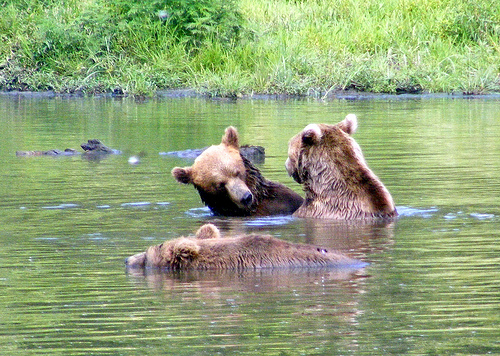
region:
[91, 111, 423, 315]
bears in the water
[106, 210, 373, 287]
bear that is almost completely submerged in the water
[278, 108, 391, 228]
head sticking out of the water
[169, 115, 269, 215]
head tilted to the side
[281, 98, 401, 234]
brown fur on the bear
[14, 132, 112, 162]
rocks sticking out of the water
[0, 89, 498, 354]
green body of water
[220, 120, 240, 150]
ear sticking off the top of the head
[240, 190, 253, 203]
black nose on the snout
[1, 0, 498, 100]
vegetation along the shore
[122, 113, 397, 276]
Three brown bears in water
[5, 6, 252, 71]
Green bushes along water's edge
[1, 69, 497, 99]
Green grass along water's edge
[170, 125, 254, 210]
Brown bear's head and face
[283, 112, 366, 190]
Brown bear facing away from camera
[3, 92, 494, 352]
Water reflecting the green grass and bushes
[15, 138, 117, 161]
Black and gray rocks in the water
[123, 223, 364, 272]
Brown bear partially submerged in water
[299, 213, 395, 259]
Reflection of brown bear in water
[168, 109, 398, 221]
Two bears next to each other in the water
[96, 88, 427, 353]
Three bears in the water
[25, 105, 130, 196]
The water is calm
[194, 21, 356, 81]
The weeds are green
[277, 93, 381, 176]
The bear has 2 ears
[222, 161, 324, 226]
The bear is wet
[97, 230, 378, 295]
The bear is mostly in the water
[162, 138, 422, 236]
The bears are togetehr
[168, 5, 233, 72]
The leaves are green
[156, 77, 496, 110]
The bank of the water is green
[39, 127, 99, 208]
There are rocks in the water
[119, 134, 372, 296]
three bears in water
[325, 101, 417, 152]
water is clear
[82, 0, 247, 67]
green plants on hill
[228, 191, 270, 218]
bear has black nose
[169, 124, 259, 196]
bear has brown ears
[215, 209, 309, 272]
bear has dark brown fur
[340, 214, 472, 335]
small ripples in water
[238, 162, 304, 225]
dark brown and wet fur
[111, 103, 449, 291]
Three bears in the foreground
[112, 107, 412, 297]
Bears are in water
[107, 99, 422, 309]
The bears are brown in color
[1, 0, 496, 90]
Tall grass in the background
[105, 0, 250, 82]
A small bush in the background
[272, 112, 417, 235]
Bear is turned away from the camera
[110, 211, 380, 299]
A side view of a bear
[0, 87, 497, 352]
A body of water in the foreground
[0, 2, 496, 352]
Photo was taken in the daytime